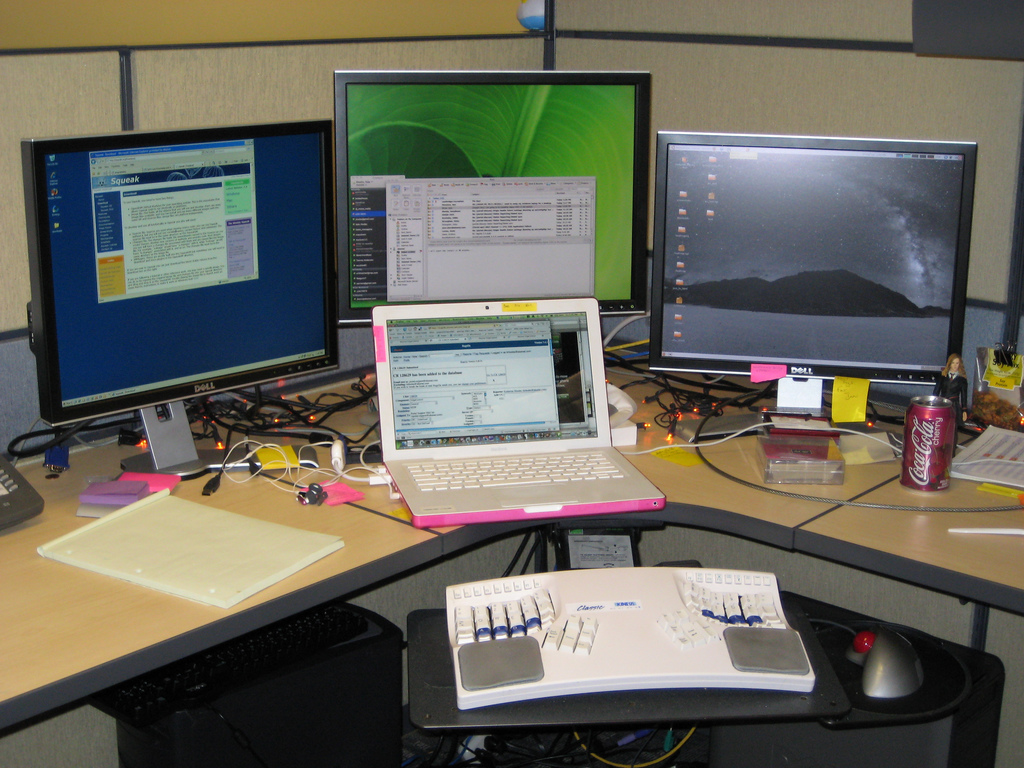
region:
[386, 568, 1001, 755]
Computer keyboard and mouse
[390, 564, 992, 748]
Computer keyboard and mouse on black shelf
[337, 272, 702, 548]
Laptop computer on desk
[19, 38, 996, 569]
Laptop computer on desk with monitors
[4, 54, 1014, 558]
Laptop computer on desk three monitors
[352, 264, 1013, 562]
Laptop computer on desk with Coke can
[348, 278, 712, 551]
Pink and white laptop computer on desk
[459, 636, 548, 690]
the grey wrist pads on the keyboard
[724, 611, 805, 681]
the grey wrist pads on the keyboard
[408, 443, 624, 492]
the white keyboard of the laptop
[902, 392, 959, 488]
the can of coca cola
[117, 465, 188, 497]
a pink pad of post-its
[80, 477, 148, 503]
a purple pad of post-its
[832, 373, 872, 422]
a yellow sticky note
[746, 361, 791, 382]
a pink sticky note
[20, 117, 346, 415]
a flat computer monitor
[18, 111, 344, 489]
monitor is on the desk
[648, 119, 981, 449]
monitor is on the desk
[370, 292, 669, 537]
laptop is on the desk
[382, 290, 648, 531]
pink and white laptop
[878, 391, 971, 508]
can is on the desk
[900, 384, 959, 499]
white and red can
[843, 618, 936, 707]
black and red mouse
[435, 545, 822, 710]
grey and white keyboard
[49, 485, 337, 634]
note pad is yellow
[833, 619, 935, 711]
grey mouse with red ball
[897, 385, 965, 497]
can of coca cola on desk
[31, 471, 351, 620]
white paper on wooden desk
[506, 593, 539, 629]
button on the keyboard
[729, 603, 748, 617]
button on the keyboard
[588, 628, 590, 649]
button on the keyboard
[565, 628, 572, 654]
button on the keyboard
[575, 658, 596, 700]
button on the keyboard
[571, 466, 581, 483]
button on the keyboard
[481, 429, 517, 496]
button on the keyboard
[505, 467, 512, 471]
button on the keyboard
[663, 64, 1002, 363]
a monitor ont he table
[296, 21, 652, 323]
a monitor on the table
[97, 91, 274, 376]
a monitor ont he table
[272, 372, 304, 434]
a cord on the table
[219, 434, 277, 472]
post it notes on the table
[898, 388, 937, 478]
a can on the table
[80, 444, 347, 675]
paper on the table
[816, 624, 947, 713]
a mouse on the table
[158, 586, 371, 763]
a desktop tower under the table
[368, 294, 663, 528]
an Apple MacBook computer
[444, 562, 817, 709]
a white ergonomic keyboard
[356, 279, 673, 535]
pink and white laptop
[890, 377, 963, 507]
red colored can of coca cola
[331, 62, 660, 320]
monitor with green background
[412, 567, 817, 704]
a white computer keyboard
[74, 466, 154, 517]
a purple note pad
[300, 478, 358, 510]
a pink note pad on a desk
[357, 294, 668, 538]
a white and pink laptop computer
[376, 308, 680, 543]
a laptop computer on a desk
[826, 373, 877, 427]
a yellow note on a computer monitor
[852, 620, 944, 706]
a silver computer mouse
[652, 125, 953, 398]
a computer monitor with notes stuck to it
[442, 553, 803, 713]
this is a large keyboard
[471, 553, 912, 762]
the keyboard is white